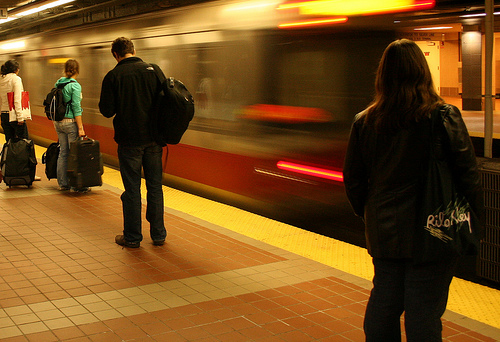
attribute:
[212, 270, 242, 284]
paint — yellow 